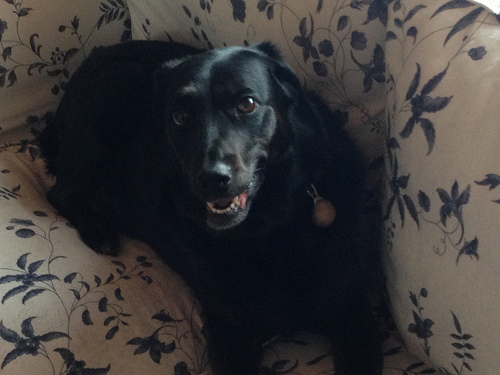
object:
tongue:
[239, 193, 246, 208]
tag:
[303, 183, 336, 226]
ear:
[266, 54, 317, 159]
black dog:
[44, 38, 384, 373]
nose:
[196, 167, 236, 193]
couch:
[8, 0, 495, 374]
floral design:
[438, 177, 471, 237]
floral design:
[358, 42, 386, 97]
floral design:
[405, 310, 435, 353]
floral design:
[127, 318, 177, 368]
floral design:
[0, 250, 58, 310]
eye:
[237, 94, 257, 114]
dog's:
[35, 37, 385, 373]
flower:
[4, 312, 73, 374]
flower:
[291, 15, 325, 64]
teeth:
[212, 209, 216, 213]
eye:
[172, 108, 187, 125]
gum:
[242, 192, 246, 195]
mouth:
[203, 185, 258, 226]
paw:
[88, 229, 121, 258]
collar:
[152, 66, 334, 252]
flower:
[402, 62, 456, 157]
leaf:
[446, 308, 462, 333]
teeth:
[230, 203, 235, 208]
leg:
[40, 156, 121, 257]